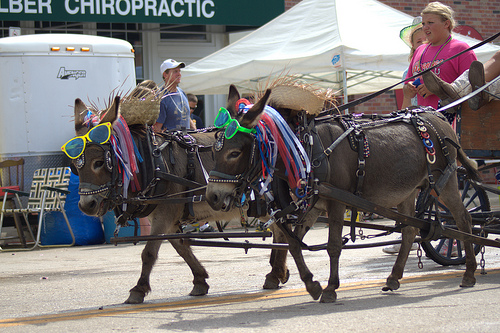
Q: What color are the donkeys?
A: They are brown.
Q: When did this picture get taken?
A: It was taken in the day time.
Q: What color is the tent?
A: The tent is white.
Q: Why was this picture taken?
A: To show the people and donkeys.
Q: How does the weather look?
A: The weather looks nice and sunny.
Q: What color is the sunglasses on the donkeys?
A: The sunglasses are green and yellow.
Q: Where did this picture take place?
A: It took place in a parade.